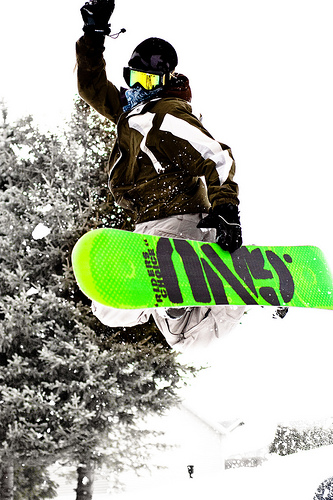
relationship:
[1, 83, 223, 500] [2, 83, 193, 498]
tree has many leaves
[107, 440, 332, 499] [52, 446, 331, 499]
snow on ground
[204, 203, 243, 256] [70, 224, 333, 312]
hand on skateboard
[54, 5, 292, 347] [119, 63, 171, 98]
man wearing goggles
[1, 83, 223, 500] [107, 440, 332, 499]
trees filled with snow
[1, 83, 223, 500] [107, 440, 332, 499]
tree filled with snow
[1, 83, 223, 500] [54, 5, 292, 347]
tree next to man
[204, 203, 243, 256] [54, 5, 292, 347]
glove of man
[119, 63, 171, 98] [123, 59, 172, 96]
goggles on man's face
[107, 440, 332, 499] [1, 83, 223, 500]
snow on tree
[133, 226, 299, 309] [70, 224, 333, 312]
letters on skateboard